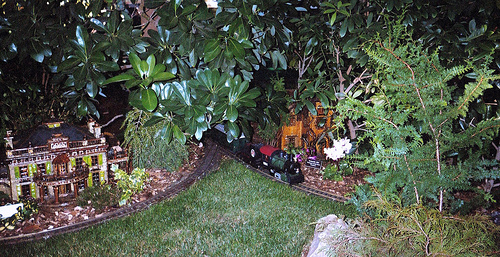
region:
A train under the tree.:
[213, 112, 306, 188]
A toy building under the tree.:
[11, 120, 122, 181]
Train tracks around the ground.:
[170, 135, 213, 191]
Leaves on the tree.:
[123, 40, 212, 97]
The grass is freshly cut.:
[177, 180, 263, 255]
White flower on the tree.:
[325, 127, 350, 160]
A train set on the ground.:
[20, 93, 337, 219]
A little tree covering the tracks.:
[345, 30, 461, 236]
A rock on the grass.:
[301, 202, 362, 248]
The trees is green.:
[46, 21, 363, 111]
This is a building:
[6, 109, 127, 218]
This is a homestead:
[15, 32, 488, 251]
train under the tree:
[231, 128, 309, 186]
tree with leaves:
[70, 26, 270, 83]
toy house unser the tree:
[3, 130, 122, 201]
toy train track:
[310, 188, 357, 202]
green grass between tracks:
[199, 194, 311, 250]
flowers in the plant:
[323, 135, 353, 164]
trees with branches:
[94, 14, 355, 84]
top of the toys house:
[7, 138, 99, 152]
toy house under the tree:
[269, 95, 331, 140]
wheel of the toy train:
[269, 170, 283, 182]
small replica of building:
[0, 115, 109, 192]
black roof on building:
[8, 113, 94, 164]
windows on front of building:
[42, 155, 94, 170]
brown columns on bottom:
[34, 185, 85, 203]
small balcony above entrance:
[38, 170, 79, 186]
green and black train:
[218, 138, 305, 190]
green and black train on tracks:
[214, 138, 297, 187]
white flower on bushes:
[321, 139, 358, 166]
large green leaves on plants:
[95, 9, 264, 122]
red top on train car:
[248, 142, 278, 160]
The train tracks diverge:
[3, 131, 365, 245]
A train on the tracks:
[208, 122, 303, 189]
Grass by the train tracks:
[1, 156, 329, 252]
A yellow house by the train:
[3, 123, 110, 188]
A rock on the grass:
[305, 211, 375, 255]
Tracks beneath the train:
[298, 178, 361, 208]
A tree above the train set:
[9, 5, 494, 255]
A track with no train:
[0, 143, 220, 241]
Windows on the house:
[11, 154, 102, 192]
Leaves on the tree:
[1, 5, 272, 105]